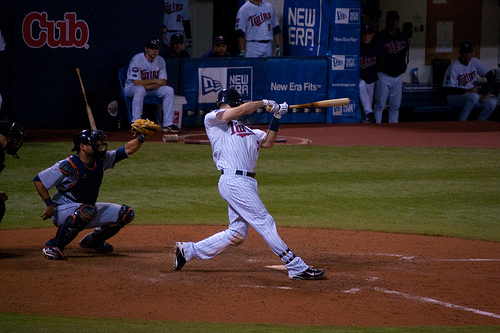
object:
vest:
[65, 153, 105, 205]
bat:
[265, 96, 352, 113]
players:
[119, 35, 184, 135]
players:
[364, 9, 411, 124]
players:
[438, 41, 498, 122]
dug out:
[0, 0, 499, 141]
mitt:
[130, 117, 164, 139]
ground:
[0, 127, 500, 333]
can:
[162, 133, 180, 143]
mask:
[88, 128, 109, 157]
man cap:
[145, 37, 162, 50]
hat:
[215, 87, 244, 108]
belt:
[221, 169, 257, 179]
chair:
[116, 65, 164, 128]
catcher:
[30, 117, 164, 263]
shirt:
[202, 108, 268, 176]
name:
[227, 119, 257, 139]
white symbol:
[197, 66, 228, 105]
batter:
[170, 87, 326, 282]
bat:
[76, 67, 99, 130]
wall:
[0, 0, 130, 128]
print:
[20, 10, 91, 51]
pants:
[172, 170, 310, 280]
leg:
[235, 188, 303, 270]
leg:
[188, 204, 250, 262]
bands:
[278, 247, 292, 259]